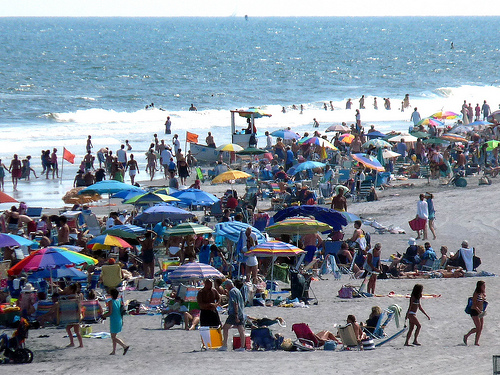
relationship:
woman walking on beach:
[402, 280, 434, 352] [3, 17, 498, 371]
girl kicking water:
[22, 155, 42, 180] [2, 16, 497, 210]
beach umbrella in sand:
[246, 237, 306, 302] [3, 173, 499, 371]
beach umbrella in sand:
[10, 243, 98, 316] [3, 173, 499, 371]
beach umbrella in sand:
[211, 167, 249, 201] [3, 173, 499, 371]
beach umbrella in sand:
[350, 152, 385, 188] [3, 173, 499, 371]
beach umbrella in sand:
[263, 213, 335, 264] [3, 173, 499, 371]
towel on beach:
[379, 288, 441, 298] [3, 17, 498, 371]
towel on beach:
[64, 328, 112, 340] [3, 17, 498, 371]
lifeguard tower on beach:
[233, 105, 272, 155] [3, 17, 498, 371]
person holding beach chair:
[61, 283, 85, 346] [32, 298, 101, 323]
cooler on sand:
[229, 330, 253, 351] [3, 173, 499, 371]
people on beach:
[10, 100, 493, 361] [3, 17, 498, 371]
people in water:
[145, 92, 413, 132] [2, 16, 497, 210]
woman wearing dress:
[100, 286, 131, 356] [105, 297, 123, 334]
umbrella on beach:
[212, 168, 251, 199] [3, 17, 498, 371]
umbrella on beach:
[264, 210, 334, 256] [3, 17, 498, 371]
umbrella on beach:
[75, 173, 142, 213] [3, 17, 498, 371]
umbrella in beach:
[212, 139, 248, 159] [8, 120, 498, 369]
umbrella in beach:
[167, 261, 225, 282] [2, 146, 498, 371]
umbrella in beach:
[77, 229, 137, 254] [77, 229, 135, 256]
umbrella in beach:
[6, 242, 100, 305] [8, 240, 104, 287]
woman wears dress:
[100, 286, 131, 356] [104, 294, 125, 335]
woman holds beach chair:
[402, 280, 434, 352] [362, 324, 411, 347]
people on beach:
[10, 100, 493, 361] [8, 120, 498, 369]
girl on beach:
[457, 275, 489, 347] [337, 223, 498, 373]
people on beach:
[210, 164, 257, 191] [75, 204, 431, 367]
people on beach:
[2, 274, 127, 368] [4, 176, 265, 372]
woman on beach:
[100, 286, 131, 356] [1, 222, 241, 372]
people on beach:
[428, 136, 493, 190] [332, 116, 499, 252]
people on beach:
[397, 134, 415, 164] [332, 116, 488, 239]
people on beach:
[253, 160, 273, 185] [184, 149, 391, 269]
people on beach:
[79, 134, 140, 179] [44, 133, 236, 223]